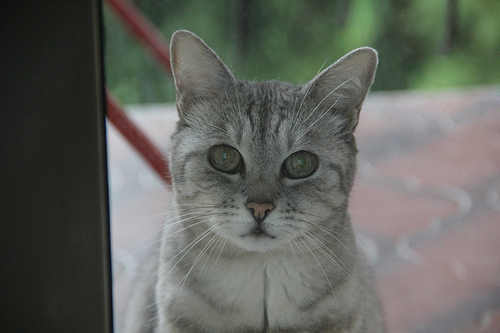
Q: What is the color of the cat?
A: White and gray.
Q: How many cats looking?
A: One.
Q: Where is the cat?
A: Behind the glass.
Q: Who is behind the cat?
A: No one.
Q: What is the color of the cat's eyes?
A: Green.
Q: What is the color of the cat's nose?
A: Flesh.